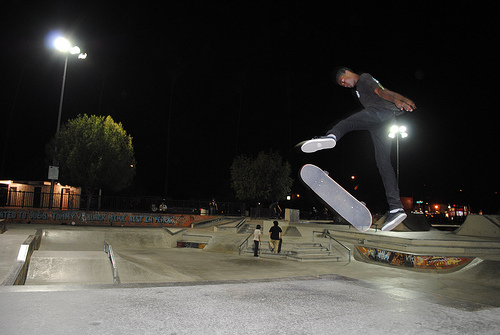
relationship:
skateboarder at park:
[333, 73, 408, 209] [127, 184, 259, 298]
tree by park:
[77, 127, 125, 208] [127, 184, 259, 298]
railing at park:
[53, 183, 116, 214] [127, 184, 259, 298]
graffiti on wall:
[103, 213, 152, 234] [41, 212, 92, 220]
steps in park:
[301, 249, 317, 260] [127, 184, 259, 298]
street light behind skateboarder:
[24, 17, 83, 141] [333, 73, 408, 209]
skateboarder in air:
[333, 73, 408, 209] [363, 10, 394, 25]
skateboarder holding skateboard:
[333, 73, 408, 209] [301, 178, 372, 222]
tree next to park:
[77, 127, 125, 208] [127, 184, 259, 298]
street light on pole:
[24, 17, 83, 141] [34, 80, 79, 101]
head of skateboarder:
[335, 67, 357, 93] [333, 73, 408, 209]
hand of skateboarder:
[396, 100, 419, 113] [333, 73, 408, 209]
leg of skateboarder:
[328, 113, 379, 137] [333, 73, 408, 209]